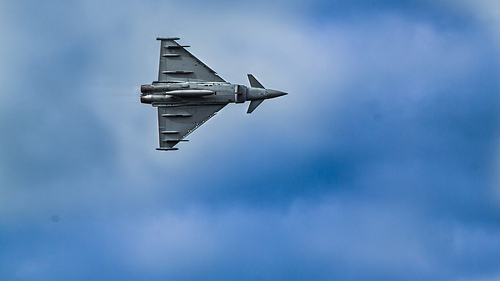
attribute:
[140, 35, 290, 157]
plane — flying, gray, military plane, flyikng, dark gray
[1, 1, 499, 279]
sky — blue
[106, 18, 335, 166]
clouds — white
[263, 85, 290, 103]
tip — sharp point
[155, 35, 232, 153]
wings — triangle shaped, small, little